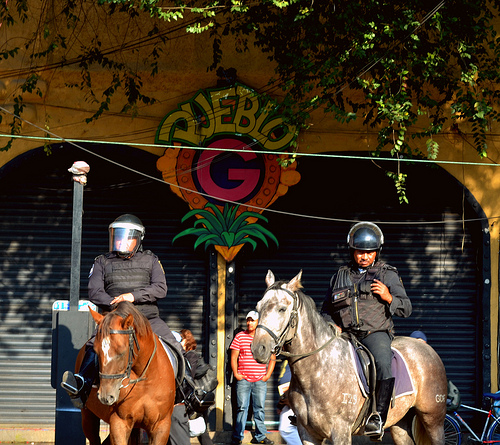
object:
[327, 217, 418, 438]
officer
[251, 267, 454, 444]
horse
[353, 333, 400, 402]
saddle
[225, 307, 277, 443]
man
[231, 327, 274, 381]
shirt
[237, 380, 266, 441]
jeans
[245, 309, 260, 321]
hat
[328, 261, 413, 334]
jacket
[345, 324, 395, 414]
pants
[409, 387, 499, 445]
bike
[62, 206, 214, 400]
man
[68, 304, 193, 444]
horse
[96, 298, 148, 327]
mane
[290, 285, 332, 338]
mane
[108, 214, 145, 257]
helmet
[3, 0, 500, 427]
building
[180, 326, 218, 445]
person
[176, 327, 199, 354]
hair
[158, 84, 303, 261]
sign